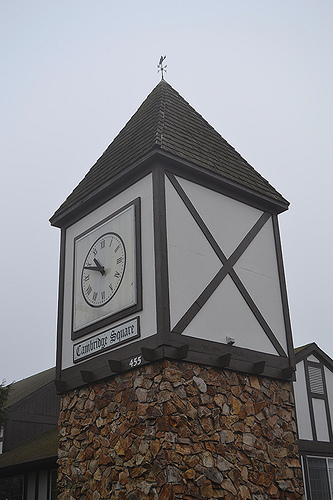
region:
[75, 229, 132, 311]
White clock on tower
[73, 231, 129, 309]
CLocks has roman numerals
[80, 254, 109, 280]
Hands of clock are black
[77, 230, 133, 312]
Border of clock is black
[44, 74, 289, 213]
Roof of tower is brown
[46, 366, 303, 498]
Wall made of stones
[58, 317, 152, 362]
Name of the street is "Cambridge Square"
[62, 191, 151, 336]
Clock is enclosed in a square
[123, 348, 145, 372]
Number below clock is 455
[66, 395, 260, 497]
Brown and gray stone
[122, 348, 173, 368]
455 on a building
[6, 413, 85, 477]
Roof on a building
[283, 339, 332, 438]
Brown and white building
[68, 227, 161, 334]
Clock on a tower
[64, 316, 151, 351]
Sign on a tower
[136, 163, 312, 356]
X on a tower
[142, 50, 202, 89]
Weather vein on a tower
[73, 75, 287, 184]
Roof on a tower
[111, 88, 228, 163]
Shingles on a tower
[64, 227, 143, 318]
The clock reads 10:49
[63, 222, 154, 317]
The clock reads 22:49 in military time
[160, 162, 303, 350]
Big wooden X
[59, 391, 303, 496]
Tower is partly made of stone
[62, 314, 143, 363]
Sign reads, "Cambridge Square."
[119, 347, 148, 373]
The number is 455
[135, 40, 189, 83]
Weathervane with arrows for each direction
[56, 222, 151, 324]
Clock has roman numerals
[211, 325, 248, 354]
Tower has a small light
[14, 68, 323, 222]
The roof has shingles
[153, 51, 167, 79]
Weather Vain on roof top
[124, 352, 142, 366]
Number 455 on building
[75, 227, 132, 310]
Clock on side of building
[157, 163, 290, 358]
Big X on side of house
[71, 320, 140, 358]
Cambridge Square sign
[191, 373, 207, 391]
Rock on side of building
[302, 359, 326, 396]
Air vent for the attic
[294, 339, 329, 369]
Peak of the roof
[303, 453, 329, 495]
Window on a house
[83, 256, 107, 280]
Hands on a clock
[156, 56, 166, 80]
Weather vane on top of a roof.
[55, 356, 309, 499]
Base of a tower made of large rock.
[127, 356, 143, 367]
The number 455.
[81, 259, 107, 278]
Black hands of a clock face.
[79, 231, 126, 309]
White and black clock on the front of a tower.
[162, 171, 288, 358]
Large wooden X on the side of a clock tower.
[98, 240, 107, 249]
Roman numeral 12 on a clock face.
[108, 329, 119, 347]
Fancy cursive S on a sign under a clock.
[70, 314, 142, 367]
Cambridge Square sign under a clock.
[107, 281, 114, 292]
Roman numeral V on a clock face.